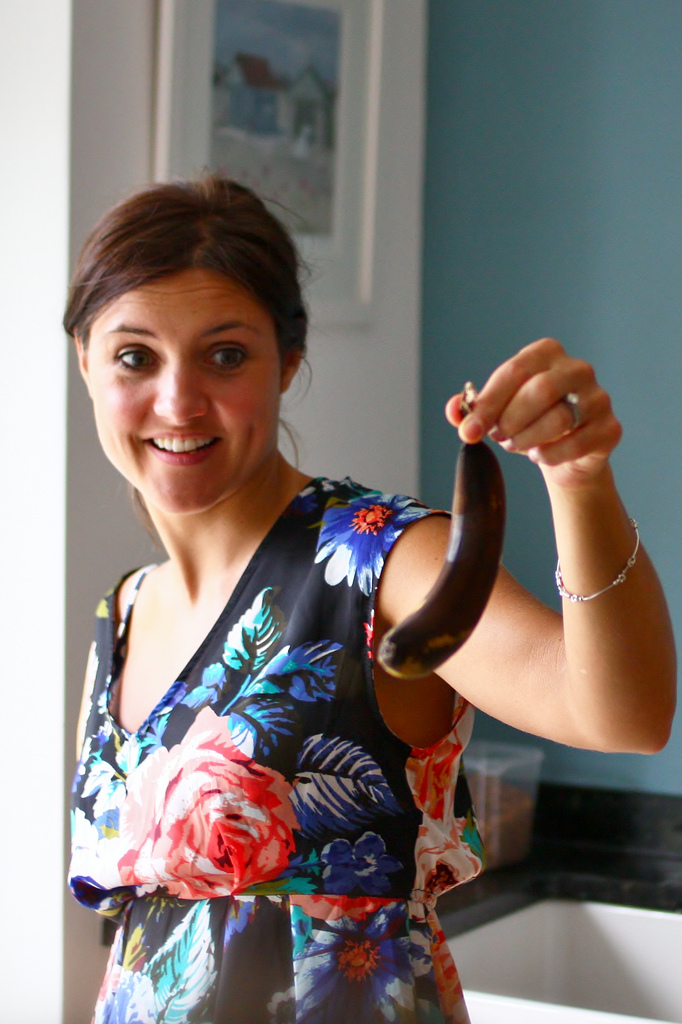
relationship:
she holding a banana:
[0, 167, 679, 1022] [377, 519, 498, 831]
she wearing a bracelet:
[62, 165, 674, 1020] [552, 519, 643, 603]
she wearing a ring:
[62, 165, 674, 1020] [569, 391, 582, 424]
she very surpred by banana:
[62, 165, 674, 1020] [378, 380, 504, 678]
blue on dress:
[278, 641, 338, 700] [66, 472, 488, 1021]